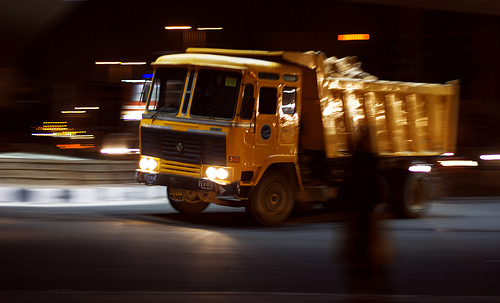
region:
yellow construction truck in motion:
[141, 40, 442, 225]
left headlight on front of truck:
[196, 159, 239, 194]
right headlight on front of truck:
[121, 137, 176, 195]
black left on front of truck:
[251, 166, 308, 227]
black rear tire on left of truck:
[394, 170, 473, 235]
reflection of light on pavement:
[133, 229, 253, 274]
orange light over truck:
[304, 15, 387, 61]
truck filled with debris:
[296, 24, 412, 141]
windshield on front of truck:
[157, 65, 242, 127]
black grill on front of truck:
[149, 125, 225, 165]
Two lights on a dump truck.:
[196, 155, 256, 190]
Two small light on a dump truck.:
[190, 155, 231, 190]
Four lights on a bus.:
[125, 145, 242, 202]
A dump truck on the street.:
[100, 36, 460, 241]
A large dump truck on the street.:
[96, 30, 472, 245]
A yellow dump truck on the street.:
[98, 31, 464, 238]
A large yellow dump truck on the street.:
[85, 28, 476, 248]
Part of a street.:
[48, 243, 186, 284]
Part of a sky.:
[30, 53, 90, 81]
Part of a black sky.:
[25, 70, 77, 100]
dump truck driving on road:
[76, 0, 480, 261]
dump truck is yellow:
[131, 8, 473, 250]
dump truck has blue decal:
[252, 122, 277, 144]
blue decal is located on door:
[254, 120, 281, 147]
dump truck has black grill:
[135, 111, 227, 170]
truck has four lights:
[134, 153, 246, 188]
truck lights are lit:
[127, 146, 243, 198]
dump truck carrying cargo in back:
[301, 25, 386, 100]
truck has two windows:
[145, 57, 255, 134]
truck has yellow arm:
[234, 56, 274, 157]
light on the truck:
[209, 163, 233, 180]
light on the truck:
[131, 157, 156, 173]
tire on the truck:
[249, 178, 292, 225]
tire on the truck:
[409, 168, 436, 215]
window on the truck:
[195, 70, 236, 122]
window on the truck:
[148, 74, 188, 116]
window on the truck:
[253, 88, 275, 110]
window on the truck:
[282, 85, 297, 119]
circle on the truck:
[251, 125, 276, 145]